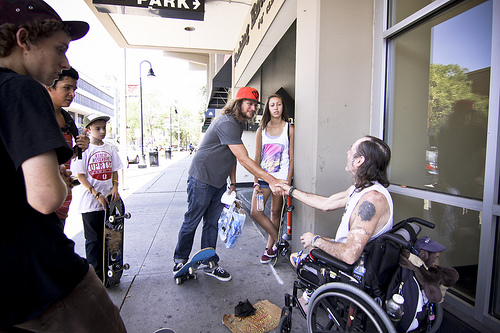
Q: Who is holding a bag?
A: The guy with a gray shirt.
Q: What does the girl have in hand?
A: A skateboard.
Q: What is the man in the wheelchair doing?
A: Shaking hands.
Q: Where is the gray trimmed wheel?
A: On the wheelchair.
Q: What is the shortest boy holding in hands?
A: A skateboard.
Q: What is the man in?
A: Wheelchair.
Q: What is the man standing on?
A: Skateboard.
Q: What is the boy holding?
A: Skateboard.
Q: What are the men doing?
A: Shaking hands.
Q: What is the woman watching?
A: The handshake.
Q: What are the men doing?
A: Shaking hands.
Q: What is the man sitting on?
A: Wheelchair.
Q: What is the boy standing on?
A: Wheelchair.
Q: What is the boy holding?
A: Skateboard.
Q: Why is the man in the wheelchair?
A: Disability.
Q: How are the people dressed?
A: Street casual.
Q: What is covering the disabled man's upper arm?
A: Tattoo.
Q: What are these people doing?
A: Watching a man.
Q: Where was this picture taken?
A: In front of a building.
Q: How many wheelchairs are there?
A: One.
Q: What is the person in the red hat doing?
A: Shaking hands.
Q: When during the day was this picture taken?
A: Daytime.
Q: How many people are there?
A: Six.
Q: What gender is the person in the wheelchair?
A: Male.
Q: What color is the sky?
A: Blue.